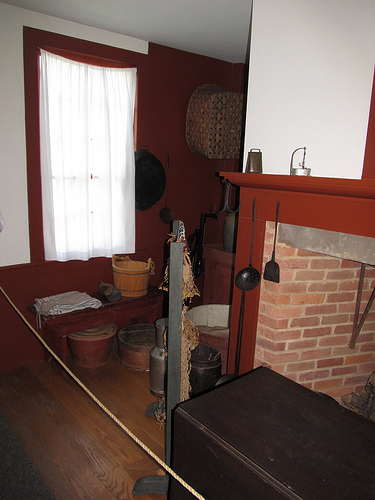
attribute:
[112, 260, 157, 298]
basket — brown, red, woven, wicker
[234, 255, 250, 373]
spoon — black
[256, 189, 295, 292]
shovel — black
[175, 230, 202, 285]
pole — blue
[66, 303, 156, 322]
bench — wood, wooden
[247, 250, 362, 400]
fireplace — brick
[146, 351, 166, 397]
jug — grey, metal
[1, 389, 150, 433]
floor — wooden, wood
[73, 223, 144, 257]
cloth — white, folded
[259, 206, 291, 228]
iron — black, large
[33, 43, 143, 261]
curtains — sheer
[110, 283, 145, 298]
bucket — wooden